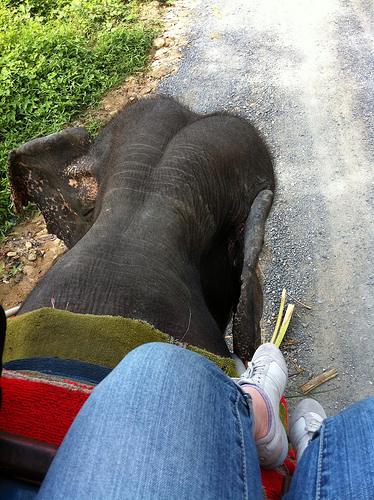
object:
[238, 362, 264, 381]
shoelaces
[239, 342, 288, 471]
foot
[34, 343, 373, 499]
person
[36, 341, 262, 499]
pant leg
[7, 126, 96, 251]
ear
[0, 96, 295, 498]
elephant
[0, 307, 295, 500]
rug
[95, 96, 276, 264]
head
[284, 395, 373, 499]
pant leg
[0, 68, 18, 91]
grass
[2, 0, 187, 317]
dirt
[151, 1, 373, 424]
road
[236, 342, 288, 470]
tennis shoe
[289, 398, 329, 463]
tennis shoe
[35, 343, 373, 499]
jeans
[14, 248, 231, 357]
back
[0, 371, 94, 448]
stripe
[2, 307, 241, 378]
stripe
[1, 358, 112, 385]
stripe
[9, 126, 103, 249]
area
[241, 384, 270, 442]
ankle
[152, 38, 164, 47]
rock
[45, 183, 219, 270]
neck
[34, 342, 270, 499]
leg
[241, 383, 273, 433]
sock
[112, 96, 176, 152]
bump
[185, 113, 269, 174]
bump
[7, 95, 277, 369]
skin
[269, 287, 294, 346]
straw